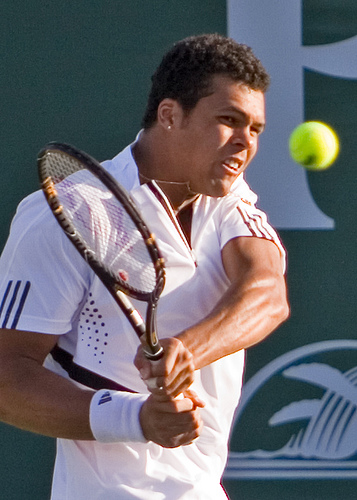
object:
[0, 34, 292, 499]
man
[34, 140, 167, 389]
racket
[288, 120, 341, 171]
ball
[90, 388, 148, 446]
wrist band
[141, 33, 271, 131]
hair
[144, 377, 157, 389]
bandage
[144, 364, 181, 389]
finger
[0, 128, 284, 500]
shirt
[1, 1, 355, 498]
wall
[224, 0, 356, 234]
letter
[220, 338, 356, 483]
picture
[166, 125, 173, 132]
earring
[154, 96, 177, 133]
ear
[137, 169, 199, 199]
necklace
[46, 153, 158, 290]
strings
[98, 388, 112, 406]
adidas logo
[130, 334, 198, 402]
hand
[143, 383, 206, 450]
hand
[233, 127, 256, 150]
nose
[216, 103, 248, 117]
eyebrow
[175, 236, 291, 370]
arm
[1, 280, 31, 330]
stripes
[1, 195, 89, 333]
sleeve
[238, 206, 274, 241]
stripes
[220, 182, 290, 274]
sleeve